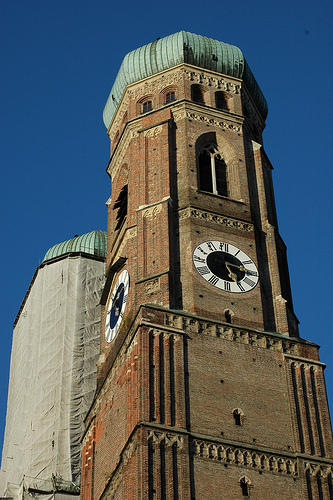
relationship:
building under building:
[0, 230, 97, 497] [0, 230, 107, 500]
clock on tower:
[188, 236, 274, 310] [89, 32, 329, 499]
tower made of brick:
[89, 32, 329, 499] [151, 150, 172, 178]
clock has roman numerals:
[188, 236, 274, 310] [191, 247, 221, 288]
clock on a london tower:
[188, 236, 274, 310] [89, 32, 329, 499]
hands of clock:
[224, 261, 256, 287] [188, 236, 274, 310]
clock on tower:
[100, 274, 139, 335] [89, 32, 329, 499]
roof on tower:
[99, 34, 261, 121] [89, 32, 329, 499]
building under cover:
[0, 230, 107, 500] [51, 260, 99, 402]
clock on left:
[100, 274, 139, 335] [106, 234, 123, 272]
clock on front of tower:
[188, 236, 274, 310] [89, 32, 329, 499]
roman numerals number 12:
[191, 247, 221, 288] [219, 240, 234, 252]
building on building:
[0, 230, 107, 500] [0, 230, 97, 497]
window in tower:
[228, 402, 256, 430] [89, 32, 329, 499]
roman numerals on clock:
[191, 247, 221, 288] [188, 236, 274, 310]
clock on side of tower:
[100, 274, 139, 335] [89, 32, 329, 499]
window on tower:
[228, 402, 256, 430] [89, 32, 329, 499]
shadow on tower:
[242, 131, 278, 328] [89, 32, 329, 499]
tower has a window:
[89, 32, 329, 499] [228, 402, 256, 430]